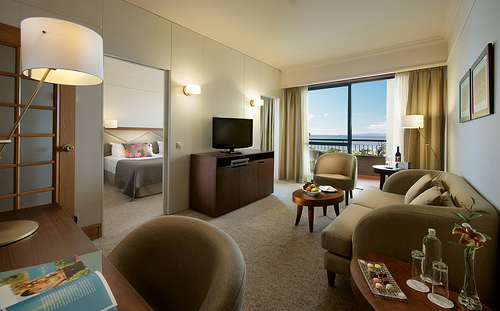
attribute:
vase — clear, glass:
[460, 245, 485, 307]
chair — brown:
[312, 149, 359, 205]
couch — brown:
[321, 166, 498, 288]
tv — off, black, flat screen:
[211, 117, 254, 152]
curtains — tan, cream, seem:
[279, 84, 309, 180]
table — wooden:
[349, 250, 480, 310]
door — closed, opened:
[1, 26, 76, 220]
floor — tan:
[95, 178, 373, 307]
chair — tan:
[108, 212, 246, 307]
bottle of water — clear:
[422, 229, 442, 281]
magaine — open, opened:
[0, 251, 118, 309]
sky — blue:
[308, 78, 389, 137]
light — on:
[172, 65, 213, 98]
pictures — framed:
[457, 44, 493, 123]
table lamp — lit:
[1, 16, 105, 244]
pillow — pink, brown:
[124, 142, 152, 157]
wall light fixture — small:
[251, 96, 266, 110]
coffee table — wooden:
[291, 184, 343, 232]